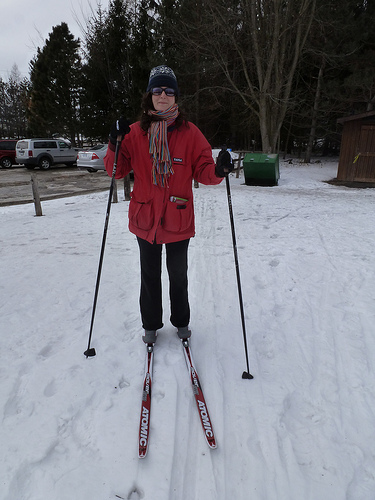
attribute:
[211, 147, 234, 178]
glove — black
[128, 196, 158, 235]
pocket — bulges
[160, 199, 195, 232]
pocket — bulges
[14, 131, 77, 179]
suv — grey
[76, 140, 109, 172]
silver car — parked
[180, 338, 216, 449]
ski — cross country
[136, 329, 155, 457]
ski — cross country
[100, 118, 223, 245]
coat — red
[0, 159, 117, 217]
fence — wooden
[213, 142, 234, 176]
hand — gloved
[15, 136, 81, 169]
suv — white, silver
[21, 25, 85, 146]
tree — pine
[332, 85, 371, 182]
cabin — brown, wooden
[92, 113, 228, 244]
coat — red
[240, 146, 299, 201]
garbage can — green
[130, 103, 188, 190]
scarf — colorful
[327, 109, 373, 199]
wooden shed — small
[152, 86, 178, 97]
dark sunglasses — woman's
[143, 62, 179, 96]
hat — black, knit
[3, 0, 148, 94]
sky — grey